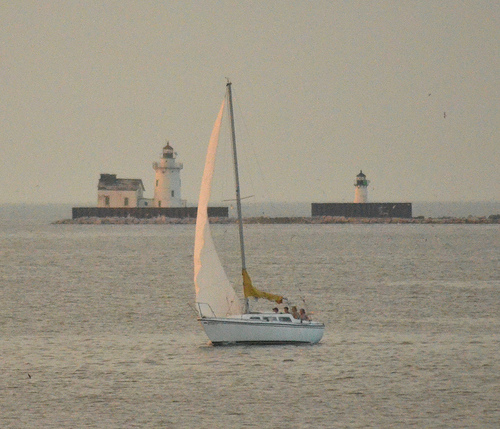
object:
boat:
[192, 79, 330, 343]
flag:
[236, 244, 292, 308]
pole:
[226, 73, 258, 319]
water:
[73, 239, 139, 305]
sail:
[193, 80, 245, 322]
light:
[144, 129, 196, 213]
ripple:
[110, 345, 121, 352]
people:
[299, 308, 310, 322]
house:
[152, 142, 187, 206]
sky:
[0, 47, 500, 204]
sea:
[76, 282, 149, 336]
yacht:
[184, 75, 328, 348]